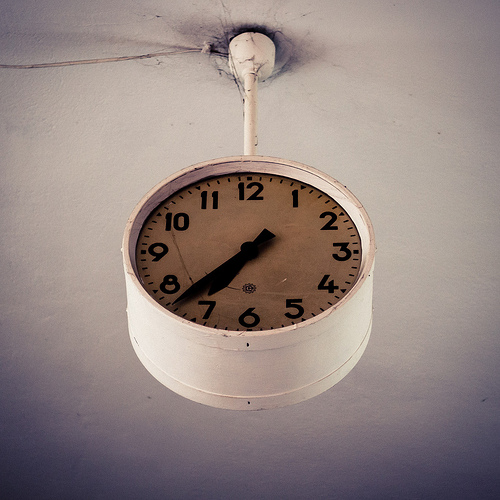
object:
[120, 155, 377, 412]
clock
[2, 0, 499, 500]
ceiling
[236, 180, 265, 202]
number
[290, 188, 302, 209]
number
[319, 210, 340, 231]
number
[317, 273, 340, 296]
number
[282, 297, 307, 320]
number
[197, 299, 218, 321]
number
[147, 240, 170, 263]
number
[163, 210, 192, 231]
number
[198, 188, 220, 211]
number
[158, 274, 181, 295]
number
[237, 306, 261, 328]
number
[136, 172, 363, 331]
face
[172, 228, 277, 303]
hand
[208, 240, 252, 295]
hand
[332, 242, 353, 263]
number